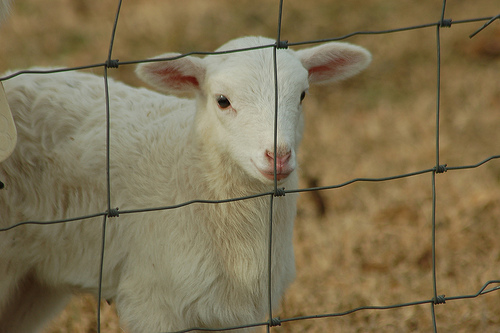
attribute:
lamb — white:
[21, 89, 290, 301]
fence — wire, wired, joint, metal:
[90, 44, 480, 226]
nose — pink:
[261, 145, 293, 170]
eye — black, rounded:
[210, 84, 244, 115]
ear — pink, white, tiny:
[163, 70, 205, 89]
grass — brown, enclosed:
[343, 188, 500, 306]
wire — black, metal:
[91, 30, 462, 75]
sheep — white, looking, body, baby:
[12, 45, 354, 220]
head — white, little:
[182, 41, 318, 178]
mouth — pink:
[248, 165, 302, 188]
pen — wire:
[46, 26, 467, 260]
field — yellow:
[111, 21, 499, 249]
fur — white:
[109, 158, 273, 283]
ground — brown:
[310, 225, 476, 332]